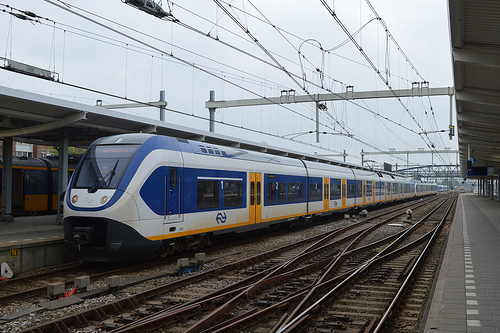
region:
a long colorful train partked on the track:
[60, 122, 441, 256]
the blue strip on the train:
[136, 161, 459, 216]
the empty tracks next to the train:
[10, 200, 455, 322]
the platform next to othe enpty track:
[420, 190, 490, 325]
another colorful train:
[11, 152, 68, 207]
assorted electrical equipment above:
[31, 10, 456, 155]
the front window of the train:
[65, 141, 130, 183]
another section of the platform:
[3, 220, 70, 264]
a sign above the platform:
[455, 160, 496, 180]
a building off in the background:
[13, 137, 43, 157]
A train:
[31, 102, 421, 264]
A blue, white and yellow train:
[36, 119, 395, 282]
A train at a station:
[28, 95, 369, 290]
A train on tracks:
[54, 106, 373, 297]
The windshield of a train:
[63, 136, 150, 213]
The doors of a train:
[229, 159, 274, 236]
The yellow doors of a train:
[238, 163, 277, 230]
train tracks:
[146, 247, 412, 324]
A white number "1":
[192, 164, 236, 206]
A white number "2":
[264, 167, 282, 194]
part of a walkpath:
[469, 237, 489, 275]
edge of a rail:
[251, 176, 300, 300]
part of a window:
[78, 150, 135, 202]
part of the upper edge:
[196, 153, 223, 161]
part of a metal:
[273, 82, 307, 105]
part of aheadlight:
[96, 193, 110, 203]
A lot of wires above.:
[135, 2, 448, 127]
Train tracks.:
[211, 256, 414, 329]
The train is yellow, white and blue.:
[51, 128, 328, 267]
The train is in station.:
[0, 75, 289, 292]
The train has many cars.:
[43, 90, 466, 281]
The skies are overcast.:
[178, 5, 410, 89]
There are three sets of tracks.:
[5, 154, 467, 331]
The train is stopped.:
[28, 92, 441, 289]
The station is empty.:
[446, 135, 499, 327]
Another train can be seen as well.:
[1, 117, 115, 233]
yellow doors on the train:
[244, 170, 266, 222]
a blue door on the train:
[163, 166, 184, 223]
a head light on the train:
[98, 194, 112, 206]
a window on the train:
[196, 175, 220, 213]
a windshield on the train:
[70, 151, 132, 188]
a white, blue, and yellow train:
[56, 125, 440, 267]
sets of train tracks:
[0, 187, 460, 332]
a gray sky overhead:
[1, 0, 459, 181]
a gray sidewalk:
[428, 190, 499, 332]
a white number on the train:
[218, 176, 227, 192]